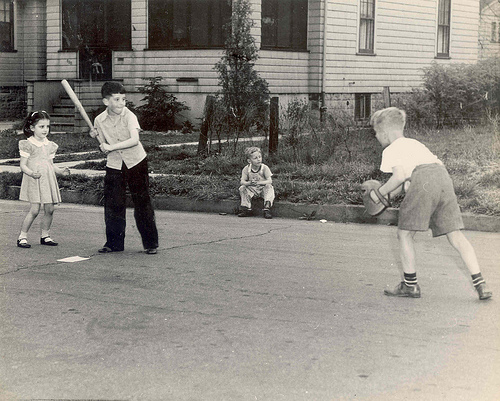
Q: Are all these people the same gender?
A: No, they are both male and female.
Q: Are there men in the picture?
A: No, there are no men.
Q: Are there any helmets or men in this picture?
A: No, there are no men or helmets.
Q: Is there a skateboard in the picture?
A: No, there are no skateboards.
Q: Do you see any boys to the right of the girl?
A: Yes, there is a boy to the right of the girl.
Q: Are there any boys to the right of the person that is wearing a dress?
A: Yes, there is a boy to the right of the girl.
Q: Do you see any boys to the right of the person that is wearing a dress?
A: Yes, there is a boy to the right of the girl.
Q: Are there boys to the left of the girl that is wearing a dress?
A: No, the boy is to the right of the girl.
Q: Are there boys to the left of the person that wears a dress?
A: No, the boy is to the right of the girl.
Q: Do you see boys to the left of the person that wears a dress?
A: No, the boy is to the right of the girl.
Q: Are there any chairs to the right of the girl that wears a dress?
A: No, there is a boy to the right of the girl.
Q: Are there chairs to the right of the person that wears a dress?
A: No, there is a boy to the right of the girl.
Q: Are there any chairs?
A: No, there are no chairs.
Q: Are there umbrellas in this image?
A: No, there are no umbrellas.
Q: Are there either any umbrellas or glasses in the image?
A: No, there are no umbrellas or glasses.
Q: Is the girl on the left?
A: Yes, the girl is on the left of the image.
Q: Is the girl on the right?
A: No, the girl is on the left of the image.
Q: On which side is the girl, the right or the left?
A: The girl is on the left of the image.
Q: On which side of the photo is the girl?
A: The girl is on the left of the image.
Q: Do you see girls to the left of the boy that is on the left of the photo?
A: Yes, there is a girl to the left of the boy.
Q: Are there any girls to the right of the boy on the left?
A: No, the girl is to the left of the boy.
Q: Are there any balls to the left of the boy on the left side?
A: No, there is a girl to the left of the boy.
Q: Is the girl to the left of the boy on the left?
A: Yes, the girl is to the left of the boy.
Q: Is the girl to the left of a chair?
A: No, the girl is to the left of the boy.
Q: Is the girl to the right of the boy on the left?
A: No, the girl is to the left of the boy.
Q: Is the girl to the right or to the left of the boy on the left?
A: The girl is to the left of the boy.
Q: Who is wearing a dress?
A: The girl is wearing a dress.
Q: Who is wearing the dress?
A: The girl is wearing a dress.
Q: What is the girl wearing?
A: The girl is wearing a dress.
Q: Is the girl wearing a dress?
A: Yes, the girl is wearing a dress.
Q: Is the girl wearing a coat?
A: No, the girl is wearing a dress.